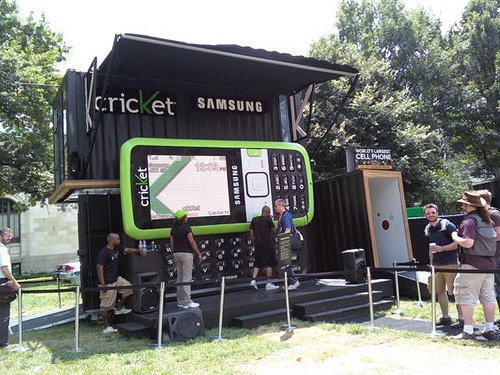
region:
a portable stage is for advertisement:
[42, 34, 419, 336]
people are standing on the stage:
[91, 195, 309, 321]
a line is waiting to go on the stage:
[351, 194, 498, 329]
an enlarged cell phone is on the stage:
[121, 135, 315, 238]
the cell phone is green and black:
[116, 133, 314, 239]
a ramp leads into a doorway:
[355, 163, 442, 302]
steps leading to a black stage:
[120, 286, 394, 339]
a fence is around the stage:
[6, 267, 498, 347]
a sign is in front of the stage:
[273, 229, 298, 336]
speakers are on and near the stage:
[123, 241, 370, 340]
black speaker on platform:
[337, 241, 371, 288]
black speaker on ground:
[158, 305, 215, 345]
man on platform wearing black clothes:
[244, 203, 275, 290]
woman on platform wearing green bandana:
[163, 203, 216, 319]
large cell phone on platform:
[116, 130, 316, 237]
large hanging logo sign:
[186, 91, 289, 126]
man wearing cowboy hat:
[450, 190, 499, 349]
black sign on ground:
[271, 230, 303, 349]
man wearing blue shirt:
[419, 198, 460, 335]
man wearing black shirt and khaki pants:
[93, 228, 142, 339]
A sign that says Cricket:
[84, 74, 178, 127]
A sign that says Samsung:
[189, 86, 269, 120]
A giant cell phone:
[116, 126, 326, 281]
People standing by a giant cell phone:
[92, 198, 331, 307]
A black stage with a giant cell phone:
[34, 36, 421, 346]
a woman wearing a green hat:
[167, 207, 194, 226]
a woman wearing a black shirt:
[163, 209, 207, 254]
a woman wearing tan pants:
[171, 252, 201, 313]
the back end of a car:
[49, 258, 85, 285]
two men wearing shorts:
[422, 249, 498, 321]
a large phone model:
[110, 131, 335, 296]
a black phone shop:
[46, 42, 370, 280]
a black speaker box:
[126, 295, 217, 362]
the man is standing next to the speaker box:
[87, 215, 171, 329]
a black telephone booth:
[346, 133, 438, 272]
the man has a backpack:
[438, 172, 493, 371]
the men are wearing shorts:
[418, 177, 495, 373]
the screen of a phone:
[141, 152, 235, 207]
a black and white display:
[329, 139, 399, 161]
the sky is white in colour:
[133, 0, 281, 37]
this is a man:
[256, 184, 306, 262]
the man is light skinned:
[461, 305, 476, 311]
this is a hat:
[459, 188, 483, 201]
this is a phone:
[112, 136, 291, 201]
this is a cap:
[165, 210, 190, 216]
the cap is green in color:
[166, 212, 191, 220]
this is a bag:
[478, 222, 496, 259]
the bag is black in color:
[288, 226, 305, 248]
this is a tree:
[399, 50, 499, 141]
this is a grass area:
[92, 350, 137, 371]